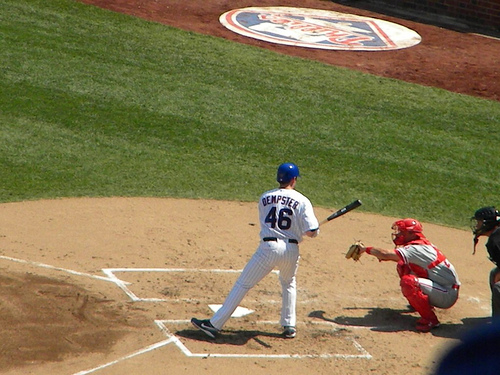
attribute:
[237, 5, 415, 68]
logo — white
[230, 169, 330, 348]
batter — batting, playing, white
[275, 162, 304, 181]
helmet — blue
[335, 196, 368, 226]
bat — black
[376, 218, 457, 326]
catcher — sqatting, squatting, playing, white, red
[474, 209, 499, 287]
umpire — standing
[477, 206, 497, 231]
hat — black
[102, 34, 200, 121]
grass — green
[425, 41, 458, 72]
dirt — brown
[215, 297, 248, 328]
plate — white